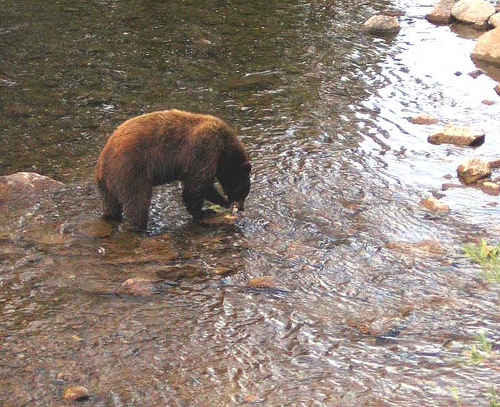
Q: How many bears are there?
A: One.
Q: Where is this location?
A: Creek.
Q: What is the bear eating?
A: Fish.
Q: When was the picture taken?
A: Daytime.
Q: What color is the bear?
A: Brown.